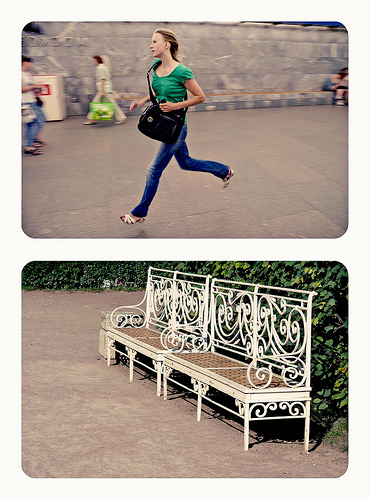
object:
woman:
[118, 28, 235, 224]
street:
[21, 106, 348, 237]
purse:
[137, 57, 189, 143]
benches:
[106, 264, 177, 383]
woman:
[82, 56, 127, 124]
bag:
[89, 97, 117, 123]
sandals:
[120, 214, 146, 224]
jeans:
[131, 120, 230, 217]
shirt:
[150, 59, 196, 116]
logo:
[21, 33, 92, 50]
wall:
[22, 22, 348, 117]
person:
[22, 56, 45, 153]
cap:
[20, 56, 31, 65]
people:
[338, 67, 349, 108]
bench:
[86, 91, 347, 116]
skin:
[194, 81, 200, 93]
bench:
[202, 283, 318, 452]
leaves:
[322, 386, 331, 399]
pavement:
[22, 289, 346, 479]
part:
[42, 314, 76, 383]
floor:
[22, 286, 346, 477]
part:
[250, 412, 304, 423]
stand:
[243, 403, 249, 452]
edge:
[248, 386, 309, 406]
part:
[274, 428, 287, 439]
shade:
[114, 337, 323, 453]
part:
[254, 306, 280, 335]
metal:
[247, 354, 308, 388]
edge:
[263, 437, 305, 446]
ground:
[22, 283, 346, 478]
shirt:
[95, 65, 112, 94]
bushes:
[154, 261, 350, 427]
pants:
[85, 93, 126, 118]